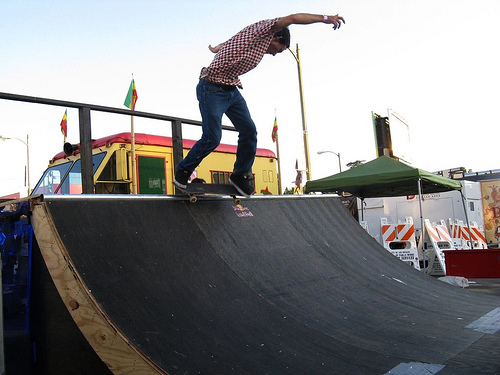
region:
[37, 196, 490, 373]
large wooden skateboard ramp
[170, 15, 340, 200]
skateboarder at the top of the ramp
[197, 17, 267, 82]
skateboarder's red plaid shirt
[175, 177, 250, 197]
a black skateboard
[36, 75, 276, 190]
a yellow food truck with red top and flags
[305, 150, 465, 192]
a green tent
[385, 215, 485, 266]
orange and white caution signs on the right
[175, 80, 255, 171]
the skateboarder's blue jeans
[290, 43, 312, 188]
a tall light pole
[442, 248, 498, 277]
a short red fence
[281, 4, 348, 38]
hand of the person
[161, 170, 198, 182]
shoe of the person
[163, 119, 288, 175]
legs of the person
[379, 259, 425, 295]
a white mark on board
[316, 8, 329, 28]
a watch to hand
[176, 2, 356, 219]
a man standing in top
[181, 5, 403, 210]
a man in air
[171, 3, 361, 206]
a man jumping into air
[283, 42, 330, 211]
a long electric poll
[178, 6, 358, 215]
man on a skateboard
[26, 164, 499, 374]
black skate ramp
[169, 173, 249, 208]
skateboard on the top of the ramp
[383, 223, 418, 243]
orange and white stripes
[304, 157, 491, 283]
small green tent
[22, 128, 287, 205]
yellow and red truck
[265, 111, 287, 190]
flag on a pole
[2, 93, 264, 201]
railing on top of the ramp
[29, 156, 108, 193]
large windows on the front of the truck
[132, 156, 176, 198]
window on the side of the truck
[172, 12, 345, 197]
a man riding a skateboard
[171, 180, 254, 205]
the man's skateboard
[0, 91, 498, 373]
a wooden skateboard ramp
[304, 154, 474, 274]
a green tent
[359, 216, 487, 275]
a group of safety barriers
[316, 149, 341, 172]
a street light in the background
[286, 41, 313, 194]
a tall street light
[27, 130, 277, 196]
a red and yellow truck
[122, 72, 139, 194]
a flag on the truck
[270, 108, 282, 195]
a flag on the truck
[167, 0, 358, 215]
a skateboarder on the top of a ramp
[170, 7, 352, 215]
a man skateboarding up a rammp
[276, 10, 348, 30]
the arm of a man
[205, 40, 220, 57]
the hand of a man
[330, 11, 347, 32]
the hand of a man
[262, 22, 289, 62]
the head of a man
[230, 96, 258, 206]
the leg of a man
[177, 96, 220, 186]
the leg of a man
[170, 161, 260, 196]
the feet of man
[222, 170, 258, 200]
the foot of man